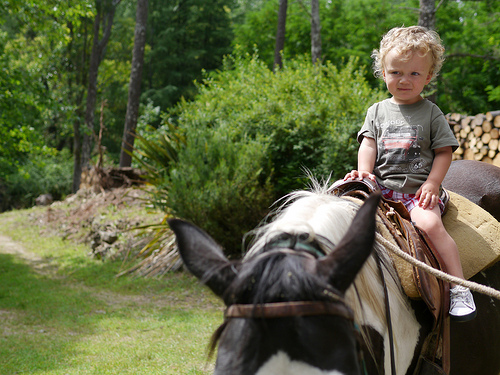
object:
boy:
[343, 25, 478, 322]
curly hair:
[369, 23, 447, 81]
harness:
[223, 301, 350, 320]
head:
[370, 26, 445, 99]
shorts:
[375, 185, 445, 216]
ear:
[319, 189, 382, 293]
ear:
[167, 217, 237, 297]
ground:
[422, 185, 455, 225]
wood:
[444, 111, 499, 169]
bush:
[123, 43, 388, 259]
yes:
[1, 236, 221, 325]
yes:
[1, 230, 226, 319]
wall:
[243, 112, 317, 177]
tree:
[71, 0, 150, 194]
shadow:
[0, 252, 138, 371]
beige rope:
[375, 231, 499, 299]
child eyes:
[392, 71, 400, 75]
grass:
[0, 206, 224, 375]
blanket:
[441, 187, 499, 280]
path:
[0, 234, 222, 312]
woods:
[22, 10, 303, 185]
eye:
[411, 71, 420, 76]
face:
[215, 320, 355, 374]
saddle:
[325, 176, 450, 374]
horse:
[163, 160, 499, 375]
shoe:
[448, 284, 477, 322]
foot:
[448, 285, 477, 322]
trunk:
[80, 166, 145, 193]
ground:
[0, 187, 225, 375]